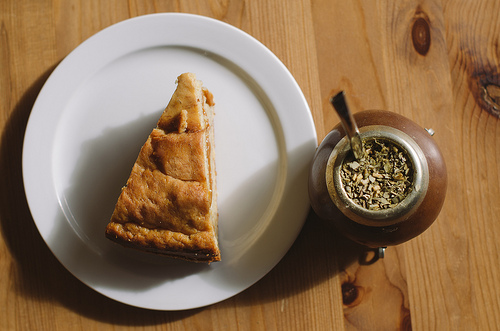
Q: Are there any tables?
A: Yes, there is a table.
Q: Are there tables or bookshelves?
A: Yes, there is a table.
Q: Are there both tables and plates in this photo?
A: Yes, there are both a table and a plate.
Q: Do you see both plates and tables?
A: Yes, there are both a table and a plate.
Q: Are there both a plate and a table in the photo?
A: Yes, there are both a table and a plate.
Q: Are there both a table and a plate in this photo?
A: Yes, there are both a table and a plate.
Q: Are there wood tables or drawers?
A: Yes, there is a wood table.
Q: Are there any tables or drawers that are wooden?
A: Yes, the table is wooden.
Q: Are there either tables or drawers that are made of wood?
A: Yes, the table is made of wood.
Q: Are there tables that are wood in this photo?
A: Yes, there is a wood table.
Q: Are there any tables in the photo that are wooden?
A: Yes, there is a table that is wooden.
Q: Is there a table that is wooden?
A: Yes, there is a table that is wooden.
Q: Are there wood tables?
A: Yes, there is a table that is made of wood.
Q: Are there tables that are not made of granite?
A: Yes, there is a table that is made of wood.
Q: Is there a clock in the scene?
A: No, there are no clocks.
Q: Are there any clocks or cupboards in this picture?
A: No, there are no clocks or cupboards.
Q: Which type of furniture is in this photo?
A: The furniture is a table.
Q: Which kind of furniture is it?
A: The piece of furniture is a table.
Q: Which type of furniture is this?
A: This is a table.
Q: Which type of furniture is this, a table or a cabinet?
A: This is a table.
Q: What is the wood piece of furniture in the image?
A: The piece of furniture is a table.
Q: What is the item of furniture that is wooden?
A: The piece of furniture is a table.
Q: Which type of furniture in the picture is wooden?
A: The furniture is a table.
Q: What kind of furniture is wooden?
A: The furniture is a table.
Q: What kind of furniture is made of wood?
A: The furniture is a table.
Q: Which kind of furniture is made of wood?
A: The furniture is a table.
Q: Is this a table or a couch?
A: This is a table.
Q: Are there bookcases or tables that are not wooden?
A: No, there is a table but it is wooden.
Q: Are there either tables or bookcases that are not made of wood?
A: No, there is a table but it is made of wood.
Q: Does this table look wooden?
A: Yes, the table is wooden.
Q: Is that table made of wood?
A: Yes, the table is made of wood.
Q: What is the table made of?
A: The table is made of wood.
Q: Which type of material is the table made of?
A: The table is made of wood.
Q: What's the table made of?
A: The table is made of wood.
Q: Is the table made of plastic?
A: No, the table is made of wood.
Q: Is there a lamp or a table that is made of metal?
A: No, there is a table but it is made of wood.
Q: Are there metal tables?
A: No, there is a table but it is made of wood.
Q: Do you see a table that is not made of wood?
A: No, there is a table but it is made of wood.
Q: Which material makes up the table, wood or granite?
A: The table is made of wood.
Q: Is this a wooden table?
A: Yes, this is a wooden table.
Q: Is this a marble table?
A: No, this is a wooden table.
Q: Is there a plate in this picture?
A: Yes, there is a plate.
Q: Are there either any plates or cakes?
A: Yes, there is a plate.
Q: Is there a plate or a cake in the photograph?
A: Yes, there is a plate.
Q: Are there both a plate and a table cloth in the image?
A: No, there is a plate but no tablecloths.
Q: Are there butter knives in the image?
A: No, there are no butter knives.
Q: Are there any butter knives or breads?
A: No, there are no butter knives or breads.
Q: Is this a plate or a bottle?
A: This is a plate.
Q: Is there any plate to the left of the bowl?
A: Yes, there is a plate to the left of the bowl.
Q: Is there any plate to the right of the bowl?
A: No, the plate is to the left of the bowl.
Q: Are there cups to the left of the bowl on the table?
A: No, there is a plate to the left of the bowl.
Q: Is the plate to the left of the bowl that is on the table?
A: Yes, the plate is to the left of the bowl.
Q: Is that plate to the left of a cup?
A: No, the plate is to the left of the bowl.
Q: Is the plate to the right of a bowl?
A: No, the plate is to the left of a bowl.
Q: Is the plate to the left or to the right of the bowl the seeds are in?
A: The plate is to the left of the bowl.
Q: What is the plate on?
A: The plate is on the table.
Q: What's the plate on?
A: The plate is on the table.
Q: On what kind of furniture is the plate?
A: The plate is on the table.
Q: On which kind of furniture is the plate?
A: The plate is on the table.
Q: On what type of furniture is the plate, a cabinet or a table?
A: The plate is on a table.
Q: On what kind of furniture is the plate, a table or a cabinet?
A: The plate is on a table.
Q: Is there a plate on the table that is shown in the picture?
A: Yes, there is a plate on the table.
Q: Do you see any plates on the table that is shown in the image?
A: Yes, there is a plate on the table.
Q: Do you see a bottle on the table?
A: No, there is a plate on the table.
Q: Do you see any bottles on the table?
A: No, there is a plate on the table.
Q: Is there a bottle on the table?
A: No, there is a plate on the table.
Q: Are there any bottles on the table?
A: No, there is a plate on the table.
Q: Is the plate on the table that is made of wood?
A: Yes, the plate is on the table.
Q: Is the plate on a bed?
A: No, the plate is on the table.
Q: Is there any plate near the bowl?
A: Yes, there is a plate near the bowl.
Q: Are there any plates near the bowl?
A: Yes, there is a plate near the bowl.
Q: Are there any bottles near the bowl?
A: No, there is a plate near the bowl.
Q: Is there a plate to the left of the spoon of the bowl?
A: Yes, there is a plate to the left of the spoon.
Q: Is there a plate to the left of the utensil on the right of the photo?
A: Yes, there is a plate to the left of the spoon.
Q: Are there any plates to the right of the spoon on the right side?
A: No, the plate is to the left of the spoon.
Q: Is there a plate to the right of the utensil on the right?
A: No, the plate is to the left of the spoon.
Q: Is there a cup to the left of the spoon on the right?
A: No, there is a plate to the left of the spoon.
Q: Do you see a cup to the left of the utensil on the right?
A: No, there is a plate to the left of the spoon.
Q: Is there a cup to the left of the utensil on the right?
A: No, there is a plate to the left of the spoon.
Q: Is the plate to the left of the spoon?
A: Yes, the plate is to the left of the spoon.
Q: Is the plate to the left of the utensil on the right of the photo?
A: Yes, the plate is to the left of the spoon.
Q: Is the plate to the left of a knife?
A: No, the plate is to the left of the spoon.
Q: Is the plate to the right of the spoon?
A: No, the plate is to the left of the spoon.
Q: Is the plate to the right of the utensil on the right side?
A: No, the plate is to the left of the spoon.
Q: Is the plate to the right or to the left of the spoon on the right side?
A: The plate is to the left of the spoon.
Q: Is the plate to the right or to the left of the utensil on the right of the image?
A: The plate is to the left of the spoon.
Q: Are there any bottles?
A: No, there are no bottles.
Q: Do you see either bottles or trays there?
A: No, there are no bottles or trays.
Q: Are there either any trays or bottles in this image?
A: No, there are no bottles or trays.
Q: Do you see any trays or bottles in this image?
A: No, there are no bottles or trays.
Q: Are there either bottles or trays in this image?
A: No, there are no bottles or trays.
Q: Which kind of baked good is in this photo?
A: The baked good is a pie.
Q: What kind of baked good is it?
A: The food is a pie.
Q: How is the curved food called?
A: The food is a pie.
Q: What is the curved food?
A: The food is a pie.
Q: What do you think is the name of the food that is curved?
A: The food is a pie.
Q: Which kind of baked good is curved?
A: The baked good is a pie.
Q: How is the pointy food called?
A: The food is a pie.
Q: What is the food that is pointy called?
A: The food is a pie.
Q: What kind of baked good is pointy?
A: The baked good is a pie.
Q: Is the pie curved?
A: Yes, the pie is curved.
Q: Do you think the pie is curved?
A: Yes, the pie is curved.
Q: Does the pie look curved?
A: Yes, the pie is curved.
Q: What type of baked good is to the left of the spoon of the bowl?
A: The food is a pie.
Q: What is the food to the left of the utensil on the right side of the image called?
A: The food is a pie.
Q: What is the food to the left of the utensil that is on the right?
A: The food is a pie.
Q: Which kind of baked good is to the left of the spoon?
A: The food is a pie.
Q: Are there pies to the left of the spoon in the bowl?
A: Yes, there is a pie to the left of the spoon.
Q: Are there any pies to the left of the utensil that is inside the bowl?
A: Yes, there is a pie to the left of the spoon.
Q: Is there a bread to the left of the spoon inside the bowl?
A: No, there is a pie to the left of the spoon.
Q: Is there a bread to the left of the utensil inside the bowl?
A: No, there is a pie to the left of the spoon.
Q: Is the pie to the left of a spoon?
A: Yes, the pie is to the left of a spoon.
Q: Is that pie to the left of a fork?
A: No, the pie is to the left of a spoon.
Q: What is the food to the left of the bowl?
A: The food is a pie.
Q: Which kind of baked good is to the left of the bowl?
A: The food is a pie.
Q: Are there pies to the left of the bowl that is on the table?
A: Yes, there is a pie to the left of the bowl.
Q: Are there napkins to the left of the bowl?
A: No, there is a pie to the left of the bowl.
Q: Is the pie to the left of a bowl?
A: Yes, the pie is to the left of a bowl.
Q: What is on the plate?
A: The pie is on the plate.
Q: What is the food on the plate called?
A: The food is a pie.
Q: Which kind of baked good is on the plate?
A: The food is a pie.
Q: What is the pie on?
A: The pie is on the plate.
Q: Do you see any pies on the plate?
A: Yes, there is a pie on the plate.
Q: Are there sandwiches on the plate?
A: No, there is a pie on the plate.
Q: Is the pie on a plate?
A: Yes, the pie is on a plate.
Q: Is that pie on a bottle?
A: No, the pie is on a plate.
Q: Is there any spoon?
A: Yes, there is a spoon.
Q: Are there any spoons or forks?
A: Yes, there is a spoon.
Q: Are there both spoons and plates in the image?
A: Yes, there are both a spoon and a plate.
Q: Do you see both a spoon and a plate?
A: Yes, there are both a spoon and a plate.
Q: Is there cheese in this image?
A: No, there is no cheese.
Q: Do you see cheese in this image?
A: No, there is no cheese.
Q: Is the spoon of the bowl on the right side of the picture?
A: Yes, the spoon is on the right of the image.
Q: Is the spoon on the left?
A: No, the spoon is on the right of the image.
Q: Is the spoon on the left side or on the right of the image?
A: The spoon is on the right of the image.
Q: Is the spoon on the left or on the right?
A: The spoon is on the right of the image.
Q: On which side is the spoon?
A: The spoon is on the right of the image.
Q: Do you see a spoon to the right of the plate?
A: Yes, there is a spoon to the right of the plate.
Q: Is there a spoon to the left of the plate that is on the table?
A: No, the spoon is to the right of the plate.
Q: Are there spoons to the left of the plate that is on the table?
A: No, the spoon is to the right of the plate.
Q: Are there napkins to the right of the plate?
A: No, there is a spoon to the right of the plate.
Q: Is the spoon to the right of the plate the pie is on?
A: Yes, the spoon is to the right of the plate.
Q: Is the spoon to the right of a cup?
A: No, the spoon is to the right of the plate.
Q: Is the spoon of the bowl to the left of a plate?
A: No, the spoon is to the right of a plate.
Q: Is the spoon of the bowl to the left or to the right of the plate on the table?
A: The spoon is to the right of the plate.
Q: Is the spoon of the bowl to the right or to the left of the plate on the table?
A: The spoon is to the right of the plate.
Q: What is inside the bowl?
A: The spoon is inside the bowl.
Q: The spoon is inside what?
A: The spoon is inside the bowl.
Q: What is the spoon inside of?
A: The spoon is inside the bowl.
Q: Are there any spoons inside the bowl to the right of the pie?
A: Yes, there is a spoon inside the bowl.